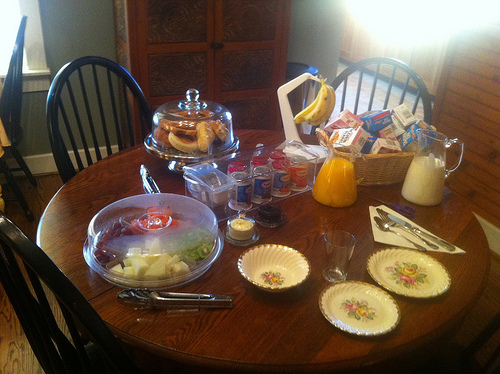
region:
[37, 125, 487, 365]
a wooden table set for breakfast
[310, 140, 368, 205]
a pitcher of orange juice on a table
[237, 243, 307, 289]
a white bowl on a table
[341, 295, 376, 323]
colorful flowers drawn on the bottom of a plate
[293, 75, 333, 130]
a bunch of bananas with brown spots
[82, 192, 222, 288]
a plastic tray with a lid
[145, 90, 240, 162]
a silver tray with a glass lid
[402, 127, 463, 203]
a pitcher of milk on a table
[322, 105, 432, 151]
a selection of cereal boxes in a wicker basket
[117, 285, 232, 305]
silver tongs on a table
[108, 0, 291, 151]
a dark brown wooden cabinet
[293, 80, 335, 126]
a bunch of yellow bananas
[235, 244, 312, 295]
a small white floral bowl on table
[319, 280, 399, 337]
a small white floral plate on table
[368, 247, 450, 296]
a small white floral plate on table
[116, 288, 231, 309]
a pair of silver tongs on table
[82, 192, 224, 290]
a covered tray of fruit and cheese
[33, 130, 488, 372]
a dark brown wooden table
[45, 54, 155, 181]
a black wooden dining room chair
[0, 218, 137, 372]
a black wooden dining room chair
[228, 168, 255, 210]
yogurt in cold case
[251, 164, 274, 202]
yogurt in cold case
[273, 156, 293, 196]
yogurt in cold case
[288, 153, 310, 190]
yogurt in cold case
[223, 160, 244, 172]
yogurt in cold case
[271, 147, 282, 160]
yogurt in cold case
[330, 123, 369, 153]
cereal box in basket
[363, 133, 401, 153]
cereal box in basket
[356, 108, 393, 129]
cereal box in basket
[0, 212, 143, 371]
a black wooden dining room chair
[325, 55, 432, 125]
a black wooden dining room chair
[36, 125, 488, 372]
a dark brown round wooden kitchen table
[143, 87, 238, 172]
a platter with donuts under a glass top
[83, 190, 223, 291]
a covered fruit and cheese tray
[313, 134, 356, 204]
a container of orange juice on the table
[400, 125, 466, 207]
a pitcher of milk on the table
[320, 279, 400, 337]
a small white floral plate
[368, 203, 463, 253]
a silverware setting on a white napkin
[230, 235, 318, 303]
THIS IS A BOWL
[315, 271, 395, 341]
THIS IS A PLATE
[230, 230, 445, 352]
THESE ARE FLORAL PRINT DISHES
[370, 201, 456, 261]
THIS IS SHINY SILVERWARE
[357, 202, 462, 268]
THE SILVERWARE IS ON THE NAPKIN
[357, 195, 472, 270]
THIS IS A WHITE NAPKIN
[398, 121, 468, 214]
THIS IS A PITCHER OF MILK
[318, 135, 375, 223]
THIS IS A PITCHER OF ORANGE JUICE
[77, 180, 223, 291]
THIS IS A CHEESE AND FRUIT TRAY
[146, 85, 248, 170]
THIS IS A DISH OF BREAD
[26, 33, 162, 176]
back of the chair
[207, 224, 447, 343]
plates on the table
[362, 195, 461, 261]
utensils next to plate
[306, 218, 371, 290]
glass on a table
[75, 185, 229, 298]
food in a bowl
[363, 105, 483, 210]
milk in the glass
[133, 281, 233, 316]
metal object on the table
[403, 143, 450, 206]
milk on the table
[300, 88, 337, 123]
banana is yellow and on the table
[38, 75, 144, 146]
the chair is black